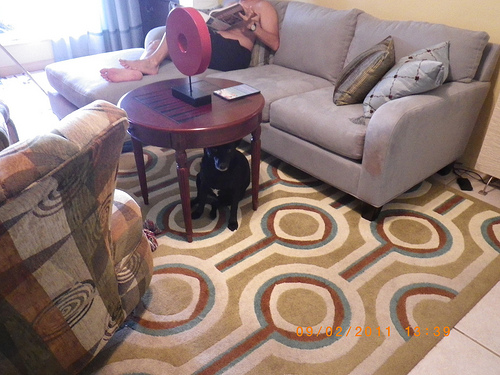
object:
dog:
[191, 148, 250, 232]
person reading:
[99, 0, 281, 83]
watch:
[247, 23, 260, 36]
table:
[117, 77, 264, 244]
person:
[100, 0, 279, 83]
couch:
[43, 0, 499, 208]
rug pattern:
[372, 271, 469, 344]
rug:
[85, 135, 498, 375]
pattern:
[238, 262, 366, 362]